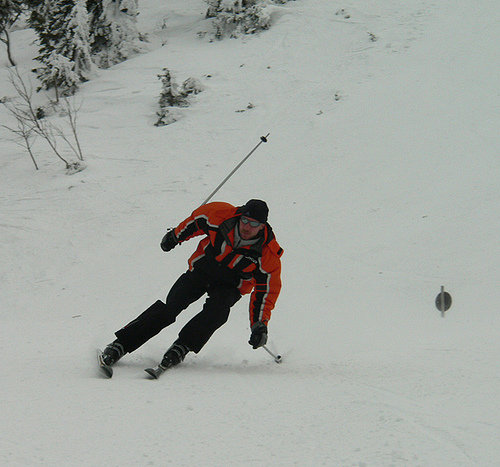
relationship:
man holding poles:
[99, 128, 301, 385] [182, 136, 309, 373]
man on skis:
[99, 128, 301, 385] [78, 349, 176, 392]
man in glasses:
[99, 128, 301, 385] [240, 217, 259, 227]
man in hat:
[99, 128, 301, 385] [237, 196, 270, 223]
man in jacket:
[99, 128, 301, 385] [175, 202, 281, 313]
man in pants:
[99, 128, 301, 385] [115, 267, 222, 346]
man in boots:
[99, 128, 301, 385] [92, 333, 196, 366]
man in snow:
[99, 128, 301, 385] [1, 3, 499, 461]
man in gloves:
[99, 128, 301, 385] [156, 230, 272, 350]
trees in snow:
[1, 0, 321, 177] [1, 3, 499, 461]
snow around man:
[1, 3, 499, 461] [99, 128, 301, 385]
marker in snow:
[432, 283, 457, 317] [1, 3, 499, 461]